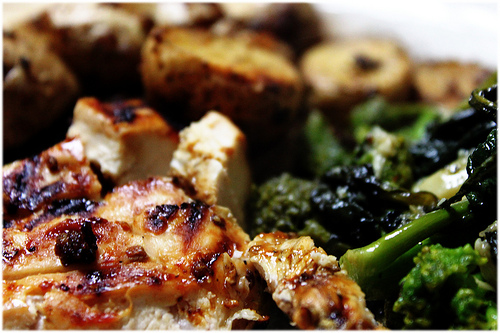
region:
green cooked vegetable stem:
[339, 196, 469, 276]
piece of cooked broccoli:
[407, 247, 487, 327]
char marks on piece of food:
[136, 199, 208, 234]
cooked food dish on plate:
[17, 99, 487, 331]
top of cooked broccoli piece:
[252, 168, 322, 238]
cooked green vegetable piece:
[452, 137, 497, 205]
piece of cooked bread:
[124, 28, 314, 134]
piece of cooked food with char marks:
[7, 161, 92, 216]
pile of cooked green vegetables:
[298, 97, 497, 329]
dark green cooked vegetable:
[314, 162, 395, 244]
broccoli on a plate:
[313, 125, 495, 315]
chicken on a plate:
[49, 122, 244, 326]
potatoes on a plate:
[108, 15, 333, 110]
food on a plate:
[22, 13, 492, 307]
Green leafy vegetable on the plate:
[285, 127, 497, 295]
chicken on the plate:
[38, 83, 286, 310]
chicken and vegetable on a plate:
[69, 92, 491, 272]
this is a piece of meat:
[22, 48, 356, 320]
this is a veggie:
[317, 148, 475, 323]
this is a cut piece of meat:
[45, 68, 256, 215]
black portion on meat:
[129, 192, 244, 259]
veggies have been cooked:
[274, 118, 494, 306]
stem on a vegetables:
[350, 197, 478, 293]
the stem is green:
[342, 183, 466, 311]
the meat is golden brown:
[112, 168, 231, 308]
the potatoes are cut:
[132, 18, 342, 144]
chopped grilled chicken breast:
[2, 96, 387, 331]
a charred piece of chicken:
[53, 221, 100, 267]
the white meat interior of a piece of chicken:
[132, 298, 186, 331]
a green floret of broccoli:
[392, 247, 492, 324]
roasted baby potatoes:
[4, 4, 498, 119]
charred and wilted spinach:
[313, 171, 489, 256]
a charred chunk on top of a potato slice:
[354, 49, 381, 76]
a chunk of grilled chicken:
[59, 96, 175, 172]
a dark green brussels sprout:
[249, 170, 319, 235]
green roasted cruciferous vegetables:
[236, 76, 498, 331]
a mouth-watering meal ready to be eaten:
[5, 4, 495, 326]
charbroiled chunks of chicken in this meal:
[4, 89, 389, 330]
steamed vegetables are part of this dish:
[251, 87, 496, 326]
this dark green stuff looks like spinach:
[306, 160, 433, 245]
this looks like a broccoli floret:
[252, 168, 325, 240]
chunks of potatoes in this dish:
[7, 5, 419, 125]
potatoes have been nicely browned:
[136, 17, 306, 132]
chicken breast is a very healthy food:
[3, 93, 380, 332]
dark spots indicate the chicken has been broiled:
[3, 136, 116, 275]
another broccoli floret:
[388, 234, 495, 326]